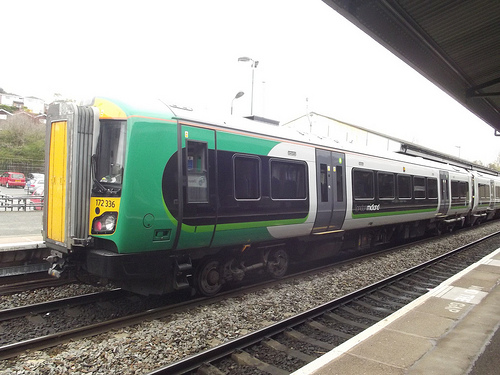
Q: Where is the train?
A: On the tracks.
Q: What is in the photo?
A: A train.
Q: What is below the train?
A: Track.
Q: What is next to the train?
A: Tracks.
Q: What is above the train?
A: The sky.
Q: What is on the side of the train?
A: Windows.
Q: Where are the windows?
A: On the train.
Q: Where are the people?
A: None in photo.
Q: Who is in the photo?
A: No people.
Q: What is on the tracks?
A: Rocks.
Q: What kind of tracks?
A: Brown.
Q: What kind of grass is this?
A: Green.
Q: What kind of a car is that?
A: Red.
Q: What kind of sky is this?
A: Light white.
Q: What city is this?
A: Chicago.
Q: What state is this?
A: Illinois.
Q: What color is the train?
A: Green, yellow, and white.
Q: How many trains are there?
A: One.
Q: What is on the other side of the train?
A: Cars.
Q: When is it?
A: Day time.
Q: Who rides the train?
A: Passengers.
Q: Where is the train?
A: On the tracks.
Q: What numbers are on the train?
A: 172 336.